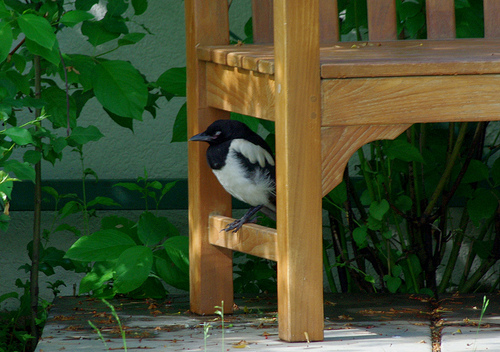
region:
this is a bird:
[180, 116, 261, 209]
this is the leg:
[233, 203, 257, 222]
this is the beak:
[189, 127, 206, 139]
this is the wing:
[235, 133, 272, 166]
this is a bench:
[257, 28, 339, 170]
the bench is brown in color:
[305, 53, 355, 123]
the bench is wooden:
[311, 50, 394, 108]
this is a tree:
[15, 20, 102, 108]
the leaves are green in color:
[63, 56, 106, 96]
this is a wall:
[106, 115, 156, 170]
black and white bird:
[189, 95, 289, 256]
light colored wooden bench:
[189, 5, 488, 327]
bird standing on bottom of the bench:
[193, 104, 289, 244]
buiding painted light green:
[17, 3, 184, 270]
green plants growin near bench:
[12, 0, 497, 325]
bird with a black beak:
[185, 105, 282, 240]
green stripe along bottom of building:
[17, 161, 279, 230]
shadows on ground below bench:
[71, 290, 458, 342]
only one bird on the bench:
[173, 78, 330, 281]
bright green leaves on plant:
[40, 49, 148, 128]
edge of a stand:
[276, 273, 303, 310]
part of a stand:
[274, 275, 309, 314]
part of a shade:
[383, 289, 415, 334]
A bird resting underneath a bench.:
[40, 16, 478, 320]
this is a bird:
[176, 117, 268, 212]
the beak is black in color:
[184, 127, 211, 144]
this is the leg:
[232, 200, 264, 232]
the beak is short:
[184, 131, 213, 143]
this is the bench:
[235, 39, 456, 259]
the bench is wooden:
[337, 72, 410, 122]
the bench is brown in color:
[309, 70, 379, 103]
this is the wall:
[106, 130, 165, 168]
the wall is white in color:
[98, 141, 145, 163]